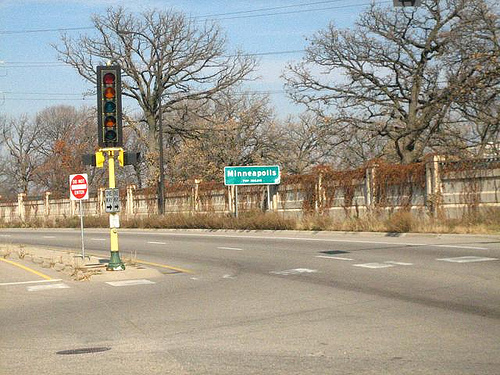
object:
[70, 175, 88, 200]
sign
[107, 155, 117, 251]
pole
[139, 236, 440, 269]
ground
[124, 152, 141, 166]
sign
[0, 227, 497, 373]
road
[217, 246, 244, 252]
lines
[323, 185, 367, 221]
wall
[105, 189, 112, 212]
sign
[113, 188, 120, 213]
sign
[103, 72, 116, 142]
lights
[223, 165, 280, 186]
green sign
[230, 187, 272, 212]
two poles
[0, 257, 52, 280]
stripe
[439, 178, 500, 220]
wall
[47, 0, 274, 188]
tree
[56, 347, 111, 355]
shadow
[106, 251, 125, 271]
base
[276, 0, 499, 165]
tree